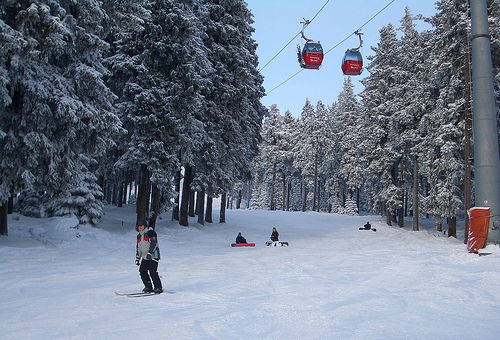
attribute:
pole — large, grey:
[444, 47, 484, 153]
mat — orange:
[452, 192, 482, 246]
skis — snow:
[108, 265, 177, 313]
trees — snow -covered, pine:
[17, 46, 202, 156]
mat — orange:
[445, 196, 483, 264]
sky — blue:
[259, 25, 295, 81]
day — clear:
[280, 71, 340, 136]